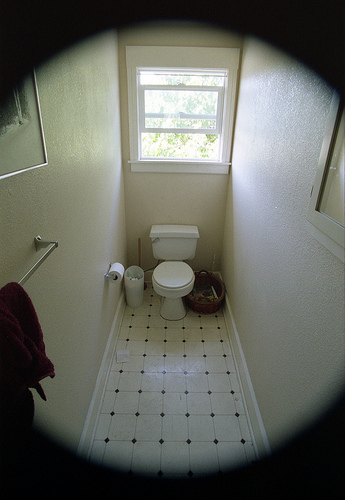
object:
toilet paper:
[108, 262, 125, 284]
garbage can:
[123, 266, 144, 307]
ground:
[250, 97, 269, 131]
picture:
[0, 67, 48, 179]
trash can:
[123, 263, 145, 307]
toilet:
[149, 223, 200, 320]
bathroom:
[1, 0, 342, 499]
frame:
[130, 63, 230, 166]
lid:
[154, 262, 193, 288]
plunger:
[138, 237, 147, 290]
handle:
[138, 235, 142, 267]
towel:
[0, 280, 58, 431]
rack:
[17, 236, 58, 286]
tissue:
[116, 348, 130, 363]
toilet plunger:
[137, 237, 148, 289]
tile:
[186, 413, 217, 443]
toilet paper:
[116, 348, 130, 363]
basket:
[184, 268, 226, 314]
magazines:
[192, 281, 219, 304]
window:
[136, 69, 227, 162]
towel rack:
[12, 237, 67, 295]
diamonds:
[164, 354, 187, 374]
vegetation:
[150, 76, 217, 156]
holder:
[104, 260, 125, 284]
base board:
[74, 268, 272, 498]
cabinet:
[303, 78, 345, 266]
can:
[124, 266, 145, 308]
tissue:
[104, 261, 125, 284]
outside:
[139, 73, 211, 147]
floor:
[87, 279, 263, 484]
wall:
[0, 23, 129, 462]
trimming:
[127, 48, 241, 176]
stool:
[149, 220, 200, 321]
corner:
[305, 200, 326, 237]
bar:
[17, 229, 59, 290]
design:
[161, 414, 189, 445]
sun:
[154, 103, 208, 153]